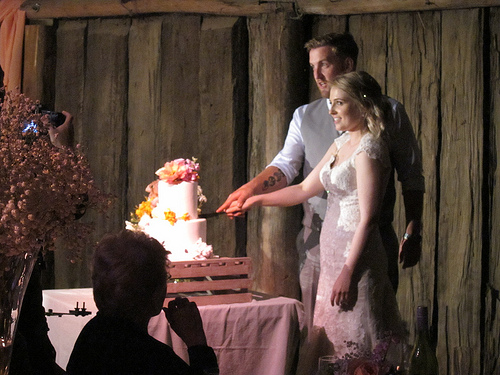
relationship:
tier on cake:
[139, 215, 206, 259] [123, 155, 213, 262]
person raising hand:
[62, 212, 242, 371] [141, 266, 253, 359]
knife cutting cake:
[196, 209, 228, 223] [123, 155, 215, 262]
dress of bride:
[308, 129, 404, 374] [225, 69, 404, 374]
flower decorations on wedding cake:
[116, 157, 215, 261] [123, 152, 215, 260]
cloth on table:
[41, 287, 305, 374] [17, 282, 306, 372]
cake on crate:
[123, 155, 213, 262] [153, 253, 252, 310]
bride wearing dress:
[225, 69, 404, 374] [315, 135, 405, 369]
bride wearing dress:
[297, 69, 466, 320] [315, 135, 405, 369]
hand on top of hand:
[202, 191, 254, 225] [226, 197, 259, 221]